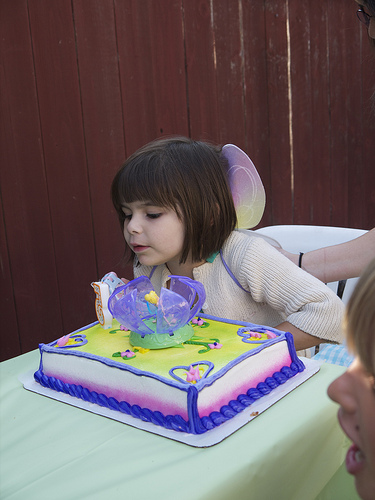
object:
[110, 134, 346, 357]
child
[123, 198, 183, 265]
face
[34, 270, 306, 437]
cake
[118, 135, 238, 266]
head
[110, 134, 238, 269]
hair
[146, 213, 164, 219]
eye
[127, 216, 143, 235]
nose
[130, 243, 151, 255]
mouth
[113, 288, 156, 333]
wing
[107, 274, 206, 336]
topper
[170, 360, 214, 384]
heart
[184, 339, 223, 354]
stem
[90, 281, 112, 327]
candle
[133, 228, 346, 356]
sweater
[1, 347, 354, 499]
table cloth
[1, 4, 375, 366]
wall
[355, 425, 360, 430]
birthmark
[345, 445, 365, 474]
top lip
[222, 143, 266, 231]
wing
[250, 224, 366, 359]
chair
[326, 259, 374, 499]
boy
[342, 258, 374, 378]
hair